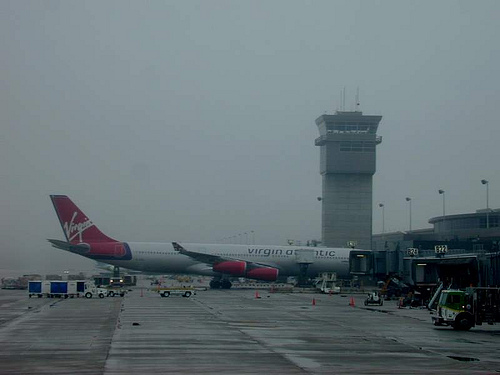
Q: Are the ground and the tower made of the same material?
A: Yes, both the ground and the tower are made of cement.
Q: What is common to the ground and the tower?
A: The material, both the ground and the tower are concrete.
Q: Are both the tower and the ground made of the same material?
A: Yes, both the tower and the ground are made of cement.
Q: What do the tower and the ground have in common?
A: The material, both the tower and the ground are concrete.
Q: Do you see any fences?
A: No, there are no fences.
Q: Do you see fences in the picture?
A: No, there are no fences.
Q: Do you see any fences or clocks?
A: No, there are no fences or clocks.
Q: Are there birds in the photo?
A: No, there are no birds.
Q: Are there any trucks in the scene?
A: Yes, there is a truck.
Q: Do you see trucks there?
A: Yes, there is a truck.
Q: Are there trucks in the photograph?
A: Yes, there is a truck.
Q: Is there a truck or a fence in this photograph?
A: Yes, there is a truck.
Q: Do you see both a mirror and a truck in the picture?
A: No, there is a truck but no mirrors.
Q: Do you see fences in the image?
A: No, there are no fences.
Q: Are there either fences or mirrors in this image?
A: No, there are no fences or mirrors.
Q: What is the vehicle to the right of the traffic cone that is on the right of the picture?
A: The vehicle is a truck.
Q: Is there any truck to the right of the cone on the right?
A: Yes, there is a truck to the right of the traffic cone.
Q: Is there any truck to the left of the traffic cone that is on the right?
A: No, the truck is to the right of the cone.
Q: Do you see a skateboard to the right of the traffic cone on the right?
A: No, there is a truck to the right of the cone.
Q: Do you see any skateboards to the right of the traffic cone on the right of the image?
A: No, there is a truck to the right of the cone.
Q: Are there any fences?
A: No, there are no fences.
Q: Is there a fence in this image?
A: No, there are no fences.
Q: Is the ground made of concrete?
A: Yes, the ground is made of concrete.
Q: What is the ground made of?
A: The ground is made of concrete.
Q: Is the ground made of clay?
A: No, the ground is made of concrete.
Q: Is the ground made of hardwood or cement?
A: The ground is made of cement.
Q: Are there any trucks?
A: Yes, there is a truck.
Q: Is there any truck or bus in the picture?
A: Yes, there is a truck.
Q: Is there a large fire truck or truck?
A: Yes, there is a large truck.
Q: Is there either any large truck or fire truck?
A: Yes, there is a large truck.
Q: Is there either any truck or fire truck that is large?
A: Yes, the truck is large.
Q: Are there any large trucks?
A: Yes, there is a large truck.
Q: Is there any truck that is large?
A: Yes, there is a truck that is large.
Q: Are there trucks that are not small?
A: Yes, there is a large truck.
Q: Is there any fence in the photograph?
A: No, there are no fences.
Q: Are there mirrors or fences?
A: No, there are no fences or mirrors.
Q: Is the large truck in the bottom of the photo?
A: Yes, the truck is in the bottom of the image.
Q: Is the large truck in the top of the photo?
A: No, the truck is in the bottom of the image.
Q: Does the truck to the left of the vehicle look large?
A: Yes, the truck is large.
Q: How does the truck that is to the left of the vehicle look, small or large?
A: The truck is large.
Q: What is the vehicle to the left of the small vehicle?
A: The vehicle is a truck.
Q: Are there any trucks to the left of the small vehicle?
A: Yes, there is a truck to the left of the vehicle.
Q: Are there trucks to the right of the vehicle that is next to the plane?
A: No, the truck is to the left of the vehicle.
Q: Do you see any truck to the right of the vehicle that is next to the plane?
A: No, the truck is to the left of the vehicle.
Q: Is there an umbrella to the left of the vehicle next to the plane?
A: No, there is a truck to the left of the vehicle.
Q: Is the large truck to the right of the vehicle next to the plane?
A: No, the truck is to the left of the vehicle.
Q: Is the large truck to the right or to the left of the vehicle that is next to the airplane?
A: The truck is to the left of the vehicle.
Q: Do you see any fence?
A: No, there are no fences.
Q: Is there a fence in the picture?
A: No, there are no fences.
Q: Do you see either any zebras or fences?
A: No, there are no fences or zebras.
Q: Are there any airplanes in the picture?
A: Yes, there is an airplane.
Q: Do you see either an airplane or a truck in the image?
A: Yes, there is an airplane.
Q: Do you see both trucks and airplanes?
A: Yes, there are both an airplane and a truck.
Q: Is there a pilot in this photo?
A: No, there are no pilots.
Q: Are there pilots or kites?
A: No, there are no pilots or kites.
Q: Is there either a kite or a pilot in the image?
A: No, there are no pilots or kites.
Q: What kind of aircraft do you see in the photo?
A: The aircraft is an airplane.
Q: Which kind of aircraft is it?
A: The aircraft is an airplane.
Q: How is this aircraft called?
A: This is an airplane.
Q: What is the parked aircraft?
A: The aircraft is an airplane.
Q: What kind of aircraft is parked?
A: The aircraft is an airplane.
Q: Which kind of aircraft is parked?
A: The aircraft is an airplane.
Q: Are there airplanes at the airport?
A: Yes, there is an airplane at the airport.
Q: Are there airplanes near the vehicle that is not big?
A: Yes, there is an airplane near the vehicle.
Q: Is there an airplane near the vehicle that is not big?
A: Yes, there is an airplane near the vehicle.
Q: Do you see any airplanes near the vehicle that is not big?
A: Yes, there is an airplane near the vehicle.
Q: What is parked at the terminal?
A: The plane is parked at the terminal.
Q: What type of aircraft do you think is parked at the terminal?
A: The aircraft is an airplane.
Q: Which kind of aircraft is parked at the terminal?
A: The aircraft is an airplane.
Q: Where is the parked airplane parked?
A: The plane is parked at the terminal.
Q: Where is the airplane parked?
A: The plane is parked at the terminal.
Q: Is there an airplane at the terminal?
A: Yes, there is an airplane at the terminal.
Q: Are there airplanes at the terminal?
A: Yes, there is an airplane at the terminal.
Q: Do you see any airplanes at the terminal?
A: Yes, there is an airplane at the terminal.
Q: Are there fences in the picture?
A: No, there are no fences.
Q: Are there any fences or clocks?
A: No, there are no fences or clocks.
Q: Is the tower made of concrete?
A: Yes, the tower is made of concrete.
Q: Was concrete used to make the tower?
A: Yes, the tower is made of concrete.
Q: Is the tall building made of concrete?
A: Yes, the tower is made of concrete.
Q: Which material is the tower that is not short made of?
A: The tower is made of concrete.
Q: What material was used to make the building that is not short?
A: The tower is made of concrete.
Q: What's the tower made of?
A: The tower is made of concrete.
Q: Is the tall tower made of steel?
A: No, the tower is made of cement.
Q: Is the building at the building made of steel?
A: No, the tower is made of concrete.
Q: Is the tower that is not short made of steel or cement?
A: The tower is made of cement.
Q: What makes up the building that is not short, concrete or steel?
A: The tower is made of concrete.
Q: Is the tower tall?
A: Yes, the tower is tall.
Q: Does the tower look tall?
A: Yes, the tower is tall.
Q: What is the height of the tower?
A: The tower is tall.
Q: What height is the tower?
A: The tower is tall.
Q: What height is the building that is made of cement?
A: The tower is tall.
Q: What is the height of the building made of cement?
A: The tower is tall.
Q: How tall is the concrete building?
A: The tower is tall.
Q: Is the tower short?
A: No, the tower is tall.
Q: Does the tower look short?
A: No, the tower is tall.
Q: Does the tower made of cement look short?
A: No, the tower is tall.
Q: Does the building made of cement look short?
A: No, the tower is tall.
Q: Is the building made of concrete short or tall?
A: The tower is tall.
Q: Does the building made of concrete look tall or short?
A: The tower is tall.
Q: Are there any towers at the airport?
A: Yes, there is a tower at the airport.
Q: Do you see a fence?
A: No, there are no fences.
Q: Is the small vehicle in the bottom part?
A: Yes, the vehicle is in the bottom of the image.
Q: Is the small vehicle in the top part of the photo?
A: No, the vehicle is in the bottom of the image.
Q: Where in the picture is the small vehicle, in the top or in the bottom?
A: The vehicle is in the bottom of the image.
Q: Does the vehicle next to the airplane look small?
A: Yes, the vehicle is small.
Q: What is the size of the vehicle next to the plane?
A: The vehicle is small.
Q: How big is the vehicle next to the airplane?
A: The vehicle is small.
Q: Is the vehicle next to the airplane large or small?
A: The vehicle is small.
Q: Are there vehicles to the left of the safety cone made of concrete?
A: Yes, there is a vehicle to the left of the traffic cone.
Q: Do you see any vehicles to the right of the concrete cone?
A: No, the vehicle is to the left of the safety cone.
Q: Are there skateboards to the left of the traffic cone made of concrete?
A: No, there is a vehicle to the left of the cone.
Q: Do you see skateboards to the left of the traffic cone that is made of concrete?
A: No, there is a vehicle to the left of the cone.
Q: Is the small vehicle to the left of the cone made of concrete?
A: Yes, the vehicle is to the left of the safety cone.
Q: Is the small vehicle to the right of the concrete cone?
A: No, the vehicle is to the left of the cone.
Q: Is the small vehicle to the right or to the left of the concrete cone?
A: The vehicle is to the left of the traffic cone.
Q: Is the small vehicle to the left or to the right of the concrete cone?
A: The vehicle is to the left of the traffic cone.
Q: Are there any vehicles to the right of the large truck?
A: Yes, there is a vehicle to the right of the truck.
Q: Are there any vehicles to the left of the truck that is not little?
A: No, the vehicle is to the right of the truck.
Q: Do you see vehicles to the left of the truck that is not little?
A: No, the vehicle is to the right of the truck.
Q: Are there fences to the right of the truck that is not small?
A: No, there is a vehicle to the right of the truck.